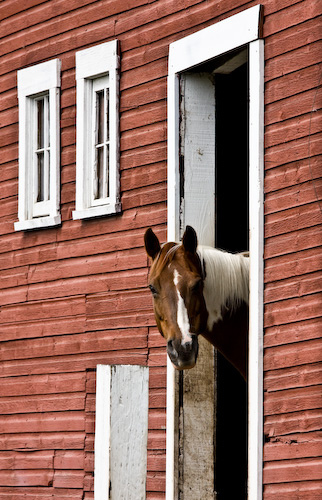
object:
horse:
[139, 225, 249, 385]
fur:
[189, 234, 249, 335]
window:
[34, 99, 44, 153]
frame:
[10, 56, 64, 236]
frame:
[70, 39, 125, 227]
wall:
[0, 0, 321, 499]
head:
[143, 225, 204, 373]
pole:
[91, 359, 149, 500]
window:
[96, 91, 105, 144]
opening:
[163, 39, 259, 500]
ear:
[143, 227, 162, 260]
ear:
[182, 223, 201, 259]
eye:
[147, 283, 160, 297]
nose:
[171, 336, 194, 357]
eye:
[189, 281, 202, 296]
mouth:
[168, 353, 201, 371]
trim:
[159, 4, 271, 500]